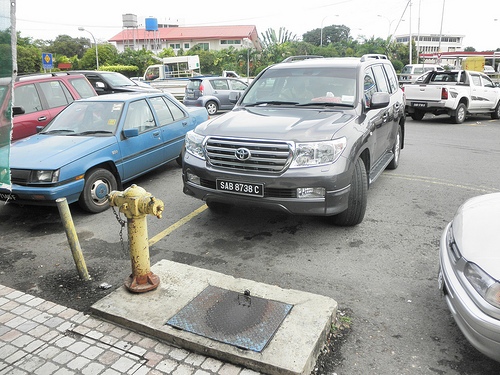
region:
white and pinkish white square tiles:
[3, 297, 93, 364]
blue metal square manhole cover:
[172, 282, 296, 349]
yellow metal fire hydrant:
[103, 185, 168, 297]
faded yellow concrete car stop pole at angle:
[58, 197, 94, 281]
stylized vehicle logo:
[232, 144, 251, 163]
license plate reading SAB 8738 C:
[216, 179, 266, 197]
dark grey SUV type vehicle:
[177, 57, 414, 215]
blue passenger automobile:
[0, 89, 215, 209]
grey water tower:
[120, 9, 138, 51]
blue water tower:
[140, 14, 162, 51]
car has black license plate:
[190, 168, 282, 211]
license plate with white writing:
[211, 173, 277, 205]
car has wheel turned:
[300, 143, 383, 235]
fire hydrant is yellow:
[100, 168, 175, 313]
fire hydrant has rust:
[111, 178, 178, 307]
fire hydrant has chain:
[101, 179, 175, 304]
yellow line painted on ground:
[136, 171, 224, 261]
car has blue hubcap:
[77, 165, 126, 214]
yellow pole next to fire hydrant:
[45, 178, 172, 298]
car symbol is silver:
[223, 130, 263, 176]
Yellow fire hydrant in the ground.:
[103, 185, 158, 292]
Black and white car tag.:
[212, 175, 266, 197]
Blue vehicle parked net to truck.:
[4, 136, 139, 183]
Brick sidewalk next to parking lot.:
[28, 293, 117, 360]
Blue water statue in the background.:
[145, 15, 164, 42]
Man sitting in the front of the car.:
[278, 73, 316, 105]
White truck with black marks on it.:
[410, 70, 496, 118]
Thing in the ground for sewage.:
[180, 272, 305, 349]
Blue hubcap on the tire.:
[95, 186, 106, 197]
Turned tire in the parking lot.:
[346, 139, 372, 219]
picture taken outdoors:
[11, 17, 465, 357]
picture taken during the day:
[38, 21, 492, 338]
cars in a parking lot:
[35, 30, 493, 321]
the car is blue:
[38, 141, 63, 161]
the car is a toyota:
[221, 103, 268, 173]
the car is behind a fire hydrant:
[66, 8, 406, 318]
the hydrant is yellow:
[97, 184, 182, 301]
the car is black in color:
[241, 83, 333, 206]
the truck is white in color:
[429, 68, 490, 108]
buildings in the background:
[101, 10, 266, 72]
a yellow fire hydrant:
[103, 178, 165, 308]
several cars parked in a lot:
[1, 67, 481, 202]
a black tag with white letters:
[196, 177, 273, 193]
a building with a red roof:
[118, 18, 267, 57]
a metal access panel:
[158, 287, 317, 353]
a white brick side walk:
[5, 283, 143, 373]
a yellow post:
[47, 184, 84, 291]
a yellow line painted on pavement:
[146, 204, 206, 254]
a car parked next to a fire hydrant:
[107, 44, 397, 296]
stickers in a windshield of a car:
[104, 99, 125, 131]